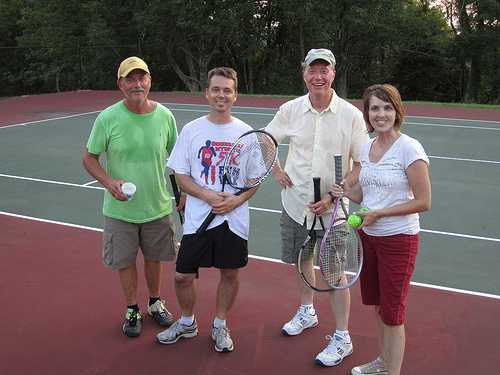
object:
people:
[82, 47, 431, 375]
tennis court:
[0, 90, 500, 375]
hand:
[352, 209, 377, 229]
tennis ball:
[347, 214, 361, 228]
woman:
[331, 83, 431, 375]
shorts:
[357, 225, 420, 326]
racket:
[318, 154, 364, 290]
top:
[358, 134, 430, 237]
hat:
[305, 48, 337, 66]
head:
[301, 48, 336, 97]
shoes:
[282, 306, 354, 366]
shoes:
[157, 317, 237, 353]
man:
[155, 66, 266, 352]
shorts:
[175, 220, 248, 269]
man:
[81, 54, 186, 338]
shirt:
[86, 99, 180, 224]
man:
[261, 48, 370, 366]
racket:
[297, 177, 341, 292]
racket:
[194, 129, 279, 234]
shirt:
[164, 115, 268, 240]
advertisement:
[197, 139, 244, 185]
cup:
[122, 182, 136, 202]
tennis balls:
[347, 208, 369, 228]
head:
[117, 56, 152, 104]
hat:
[118, 56, 150, 80]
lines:
[0, 100, 500, 302]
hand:
[107, 178, 129, 202]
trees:
[0, 1, 500, 106]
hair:
[363, 83, 405, 135]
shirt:
[264, 88, 370, 230]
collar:
[302, 88, 340, 114]